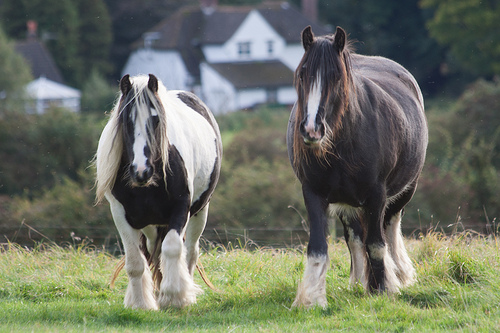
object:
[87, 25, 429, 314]
two horses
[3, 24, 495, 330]
field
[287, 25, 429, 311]
horse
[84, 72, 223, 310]
horse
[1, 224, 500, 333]
grass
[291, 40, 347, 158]
mane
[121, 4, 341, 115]
house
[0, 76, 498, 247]
bushes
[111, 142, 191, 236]
brown patches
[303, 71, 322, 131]
white accents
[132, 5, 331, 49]
roof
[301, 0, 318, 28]
fireplace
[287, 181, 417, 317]
slow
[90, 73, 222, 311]
fur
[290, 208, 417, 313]
fur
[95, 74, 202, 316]
white